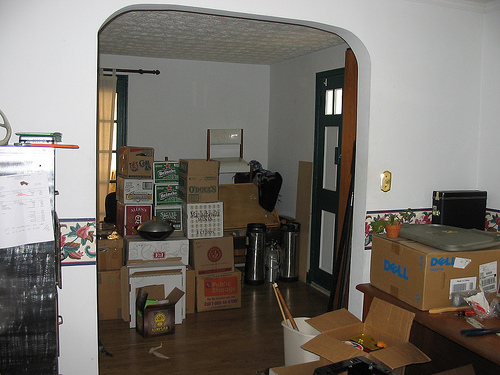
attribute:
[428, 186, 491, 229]
chest — black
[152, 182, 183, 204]
box — cardboard, closed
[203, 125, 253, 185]
chair — white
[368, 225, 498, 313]
dell box — cardboard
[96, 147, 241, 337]
boxes — stacked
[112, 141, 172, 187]
cardboard — closed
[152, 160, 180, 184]
box — closed, cardboard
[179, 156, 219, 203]
box — cardboard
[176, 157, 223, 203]
box — cardboard, brown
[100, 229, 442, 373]
floor — hard, wooden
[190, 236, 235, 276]
box — closed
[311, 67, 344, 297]
door — green and white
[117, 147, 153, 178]
box — cardboard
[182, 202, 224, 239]
box — cardboard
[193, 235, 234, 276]
box — cardboard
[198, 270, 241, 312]
box — cardboard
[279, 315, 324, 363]
bin — cream colored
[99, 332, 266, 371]
floor — cardboard